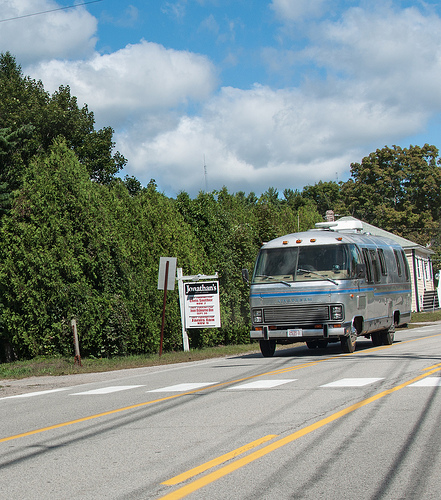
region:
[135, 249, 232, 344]
Two signs on the side of the road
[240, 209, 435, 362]
A house behind the camper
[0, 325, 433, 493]
A road with three yellow lines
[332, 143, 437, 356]
Trees behind the house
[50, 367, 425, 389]
White boxes on the road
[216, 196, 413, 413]
A camper on the road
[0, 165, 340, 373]
Trees on the side of the road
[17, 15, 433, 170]
White clouds in the sky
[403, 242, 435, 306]
Stairs in front of the house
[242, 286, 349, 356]
four head lights oncamper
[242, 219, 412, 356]
motor home driving down the road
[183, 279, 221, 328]
white sign next to motor home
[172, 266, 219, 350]
white post next to the motor home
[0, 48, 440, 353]
green foliage behind the road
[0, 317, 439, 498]
a paved road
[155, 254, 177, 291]
back of a metal road sign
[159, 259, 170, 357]
wooden post for the road sign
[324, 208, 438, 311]
small building behind the motor home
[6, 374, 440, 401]
white crosswalk in the road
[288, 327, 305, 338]
license plate on the motor home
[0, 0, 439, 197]
a cloudy blue sky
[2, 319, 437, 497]
a paved city street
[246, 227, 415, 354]
a silver van on street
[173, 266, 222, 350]
a white wooden street sign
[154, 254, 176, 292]
back of a street sign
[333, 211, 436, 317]
a house in distance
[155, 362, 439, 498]
a long yellow painted line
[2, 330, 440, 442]
a long yellow painted line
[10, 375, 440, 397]
a white painted cross walk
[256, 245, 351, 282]
a van's front windshield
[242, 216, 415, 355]
a van traveling on the road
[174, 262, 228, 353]
this appears to be a sign advertising local businesses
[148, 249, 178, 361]
a road sign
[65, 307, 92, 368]
a metal post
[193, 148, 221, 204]
the top of a radio transmission tower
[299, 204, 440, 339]
the view of the house is obstructed by the van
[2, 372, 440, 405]
a crosswalk on the road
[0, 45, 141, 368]
trees and shrubs by the roadside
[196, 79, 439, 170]
a fair weather cloud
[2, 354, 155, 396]
a driveway comming off the road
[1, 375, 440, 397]
White crosswalk markings on a road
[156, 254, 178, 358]
Back of a road sign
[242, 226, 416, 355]
A silver recreational vehicle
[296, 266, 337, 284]
Windshield wiper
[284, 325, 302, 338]
License plate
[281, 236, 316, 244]
A grouping of reflectors atop a recreational vehicle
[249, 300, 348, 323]
Front headlights of a silver colored recreational vehicle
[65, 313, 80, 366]
Metal pole on the side of a road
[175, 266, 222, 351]
A white swinging sign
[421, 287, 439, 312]
Side stairs to a small house